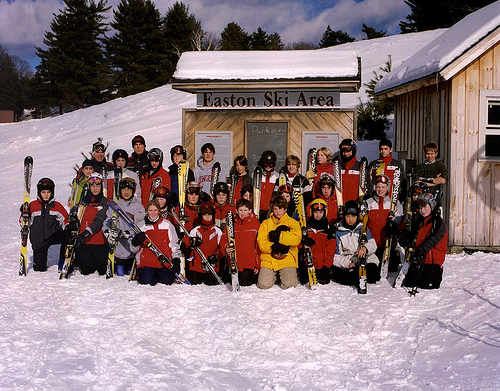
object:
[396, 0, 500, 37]
trees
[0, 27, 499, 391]
snow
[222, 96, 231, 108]
letter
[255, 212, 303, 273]
jacket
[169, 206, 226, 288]
poles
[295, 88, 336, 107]
word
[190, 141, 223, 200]
person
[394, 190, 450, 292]
child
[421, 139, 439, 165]
head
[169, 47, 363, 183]
building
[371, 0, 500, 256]
building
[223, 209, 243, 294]
ski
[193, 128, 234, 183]
rules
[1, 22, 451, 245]
ski mountain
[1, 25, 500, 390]
tracks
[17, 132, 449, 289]
group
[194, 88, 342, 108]
sign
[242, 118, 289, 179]
chalk board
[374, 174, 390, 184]
goggles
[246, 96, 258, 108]
letter n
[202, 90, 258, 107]
easton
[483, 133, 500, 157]
window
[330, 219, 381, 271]
white jacket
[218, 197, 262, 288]
boy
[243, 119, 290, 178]
door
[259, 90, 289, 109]
ski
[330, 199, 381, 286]
skier